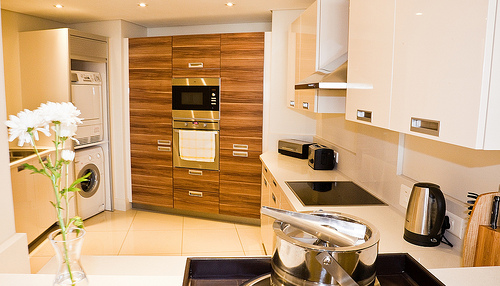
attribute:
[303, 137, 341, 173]
toaster — black, silver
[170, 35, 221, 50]
area — brown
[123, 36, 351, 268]
wall — wood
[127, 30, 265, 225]
wall — wooden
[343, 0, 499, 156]
cupboard — white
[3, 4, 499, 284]
modern kitchen — interior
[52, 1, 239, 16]
lights — glowing, recessed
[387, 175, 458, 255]
kettle — metalic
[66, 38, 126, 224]
stacked appliances — white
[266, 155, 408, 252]
table — clean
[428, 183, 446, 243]
handle — black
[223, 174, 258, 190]
area — brown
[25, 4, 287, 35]
ceiling — white